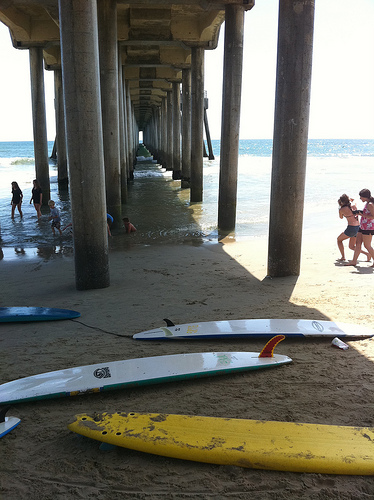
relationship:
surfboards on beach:
[4, 284, 373, 484] [0, 143, 374, 498]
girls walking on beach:
[328, 183, 373, 277] [2, 152, 373, 498]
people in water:
[5, 172, 66, 243] [2, 141, 373, 258]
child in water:
[37, 197, 69, 243] [2, 141, 373, 258]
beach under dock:
[2, 152, 373, 498] [0, 0, 316, 291]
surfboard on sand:
[67, 411, 374, 474] [3, 237, 372, 495]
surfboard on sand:
[0, 335, 293, 404] [3, 237, 372, 495]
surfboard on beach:
[132, 311, 372, 357] [0, 143, 374, 498]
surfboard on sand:
[2, 296, 86, 332] [3, 237, 372, 495]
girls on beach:
[337, 188, 374, 267] [2, 152, 373, 498]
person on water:
[30, 180, 42, 218] [2, 141, 373, 258]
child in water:
[48, 200, 62, 236] [2, 141, 373, 258]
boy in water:
[116, 213, 143, 239] [7, 139, 364, 271]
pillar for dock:
[267, 1, 315, 276] [0, 0, 316, 291]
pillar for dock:
[268, 1, 326, 283] [0, 0, 316, 291]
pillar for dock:
[56, 0, 112, 292] [0, 0, 316, 291]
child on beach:
[333, 193, 362, 267] [2, 152, 373, 498]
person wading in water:
[9, 180, 26, 224] [0, 161, 360, 247]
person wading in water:
[28, 178, 48, 218] [2, 141, 373, 258]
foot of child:
[335, 252, 347, 260] [332, 191, 361, 264]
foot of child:
[344, 254, 359, 266] [329, 193, 361, 263]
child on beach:
[337, 193, 371, 261] [2, 152, 373, 498]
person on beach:
[344, 188, 361, 269] [2, 152, 373, 498]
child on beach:
[48, 200, 62, 236] [2, 152, 373, 498]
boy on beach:
[121, 218, 137, 233] [2, 152, 373, 498]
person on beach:
[30, 180, 42, 218] [2, 152, 373, 498]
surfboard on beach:
[133, 317, 372, 338] [2, 152, 373, 498]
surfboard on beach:
[0, 306, 82, 322] [2, 152, 373, 498]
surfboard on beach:
[0, 335, 293, 404] [2, 152, 373, 498]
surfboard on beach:
[68, 407, 361, 477] [2, 152, 373, 498]